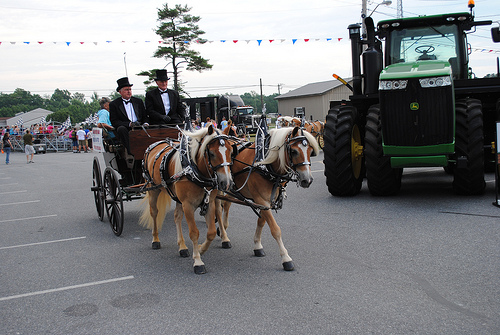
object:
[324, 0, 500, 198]
tractor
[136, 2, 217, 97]
tree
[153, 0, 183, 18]
leaves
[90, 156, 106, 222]
wheel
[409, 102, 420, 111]
logo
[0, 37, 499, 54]
pennant banner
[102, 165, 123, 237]
large wheels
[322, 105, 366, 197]
tires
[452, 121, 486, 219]
tires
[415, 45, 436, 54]
steering wheel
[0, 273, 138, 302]
lines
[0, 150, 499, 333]
pavement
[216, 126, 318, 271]
horse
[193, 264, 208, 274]
hooves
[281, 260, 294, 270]
hooves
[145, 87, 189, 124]
suits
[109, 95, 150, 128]
suits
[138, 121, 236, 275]
horse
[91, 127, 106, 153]
sign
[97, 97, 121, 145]
man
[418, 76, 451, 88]
head lights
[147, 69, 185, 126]
man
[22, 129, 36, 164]
people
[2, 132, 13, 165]
people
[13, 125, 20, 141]
people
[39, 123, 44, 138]
people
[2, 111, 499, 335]
parking lot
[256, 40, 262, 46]
flags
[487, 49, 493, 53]
flags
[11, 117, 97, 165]
crowd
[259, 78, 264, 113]
pole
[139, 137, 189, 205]
harness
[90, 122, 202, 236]
brown carriage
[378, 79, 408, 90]
headlights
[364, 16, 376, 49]
exhaust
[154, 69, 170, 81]
hat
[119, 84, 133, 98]
head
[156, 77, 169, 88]
head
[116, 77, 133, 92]
hat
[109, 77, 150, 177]
man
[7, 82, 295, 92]
power lines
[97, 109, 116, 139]
shirt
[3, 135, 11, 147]
shirt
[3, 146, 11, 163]
pants